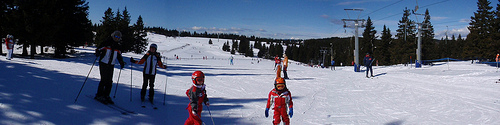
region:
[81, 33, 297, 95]
Skiers on the slopes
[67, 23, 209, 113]
Skiers at a skiing resort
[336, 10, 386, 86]
Ski lift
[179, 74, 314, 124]
Kids skiing on the slope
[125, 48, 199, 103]
Ski poles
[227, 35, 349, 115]
Trees along the ski slope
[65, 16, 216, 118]
Two adults skiing on the slopes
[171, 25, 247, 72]
Snow on the ski slope.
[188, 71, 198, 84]
Helmet on child skiing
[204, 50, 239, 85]
Snow on the ground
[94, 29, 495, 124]
several people at a ski resort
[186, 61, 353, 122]
children wearing red snow suits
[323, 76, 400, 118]
tracks on the white snow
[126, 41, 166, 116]
a woman holding ski poles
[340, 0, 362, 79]
an electrical transformer in the snow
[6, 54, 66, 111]
shadow on the ground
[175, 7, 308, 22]
the clear blue sky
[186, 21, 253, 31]
a line of fluffy white clouds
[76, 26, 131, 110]
a parent skiing on a hill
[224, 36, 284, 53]
trees growing on the slopes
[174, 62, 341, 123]
Two kids skiing on the slopes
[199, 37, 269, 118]
Snow on the ground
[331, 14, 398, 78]
The ski lift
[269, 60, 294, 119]
Child wearing a helmet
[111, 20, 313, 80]
Trees along the slope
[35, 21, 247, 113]
Skiing at a ski resort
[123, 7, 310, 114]
Nice day at the ski resort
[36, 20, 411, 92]
Lost of skiers skiing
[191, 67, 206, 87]
a red helmet on the child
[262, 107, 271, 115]
a blue glove on the child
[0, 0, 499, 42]
a blue sky over the snow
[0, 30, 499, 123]
white snow on the ground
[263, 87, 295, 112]
a red and white coat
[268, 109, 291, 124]
a red pair of pants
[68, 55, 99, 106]
a black ski pole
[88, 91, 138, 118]
a pair of skis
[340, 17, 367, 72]
a large gray ple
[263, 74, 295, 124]
a child in the snow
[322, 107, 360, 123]
small spot in white snow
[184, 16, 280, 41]
storm clouds in the sky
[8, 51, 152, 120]
large shadow on trees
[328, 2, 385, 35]
overhead ski lift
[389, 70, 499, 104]
long tracks in the snow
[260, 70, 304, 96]
orange helmet on person's head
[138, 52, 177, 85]
black and white ski jacket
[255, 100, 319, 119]
blue gloves on skier's hand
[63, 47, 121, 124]
long ski pole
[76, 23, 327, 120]
skier's standing on the white snow